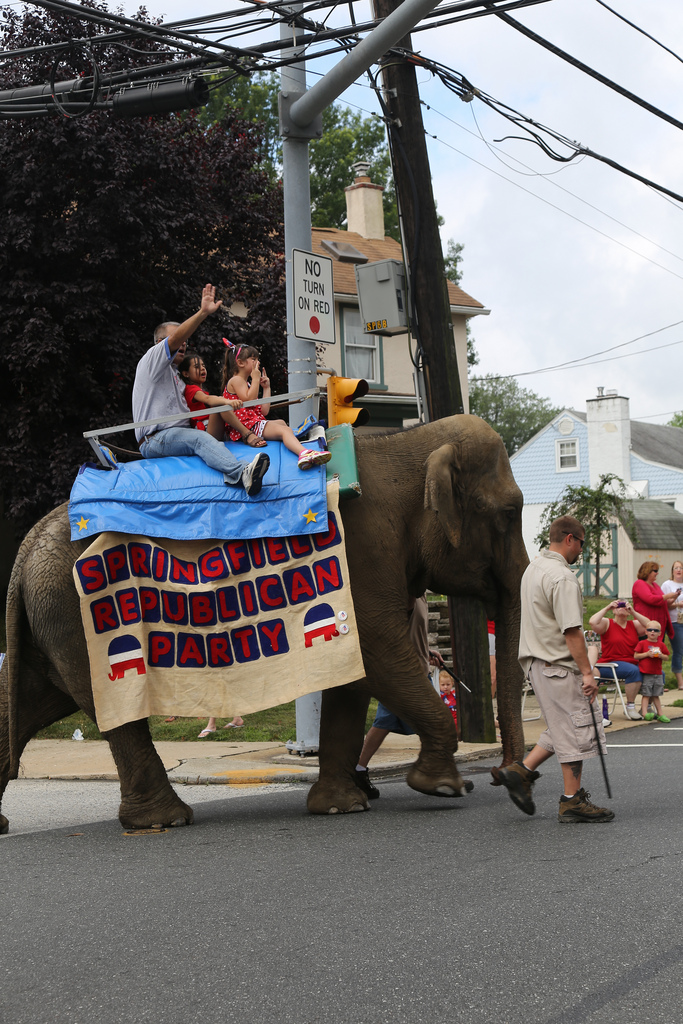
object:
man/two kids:
[132, 282, 333, 496]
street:
[0, 722, 678, 1013]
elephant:
[0, 413, 530, 835]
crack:
[606, 855, 670, 879]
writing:
[82, 518, 340, 668]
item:
[73, 477, 368, 732]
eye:
[504, 510, 515, 521]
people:
[634, 621, 672, 723]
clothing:
[596, 618, 639, 665]